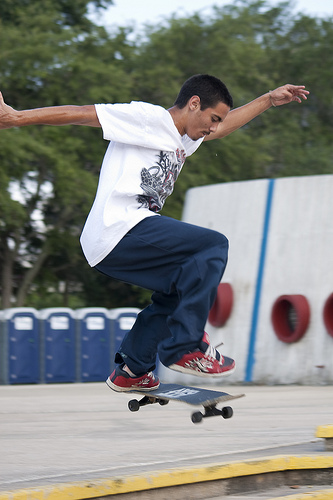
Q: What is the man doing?
A: Skateboarding.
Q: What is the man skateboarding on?
A: Raised cement platform.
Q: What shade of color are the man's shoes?
A: Red and black.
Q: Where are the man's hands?
A: Spread out before and behind him.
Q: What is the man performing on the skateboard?
A: Stunt.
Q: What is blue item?
A: Pole.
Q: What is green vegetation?
A: Trees.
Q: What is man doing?
A: Jumping.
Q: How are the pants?
A: Baggy.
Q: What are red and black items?
A: Sneakers.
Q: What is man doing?
A: Trick.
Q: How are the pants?
A: Baggy.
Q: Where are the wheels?
A: On skateboard.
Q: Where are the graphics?
A: On t-shirt.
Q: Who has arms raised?
A: Skateboarder.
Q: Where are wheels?
A: On the skateboard.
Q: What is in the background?
A: Trees.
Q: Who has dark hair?
A: Guy skateboarding.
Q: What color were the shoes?
A: Red.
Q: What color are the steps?
A: Yellow.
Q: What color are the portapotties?
A: Blue.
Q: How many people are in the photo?
A: One.